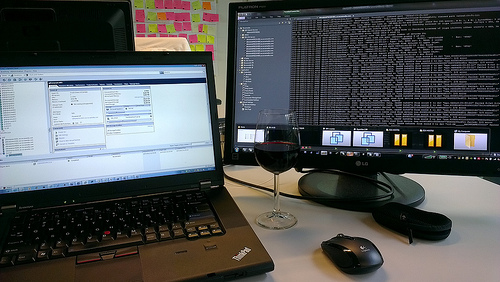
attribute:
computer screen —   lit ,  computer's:
[220, 0, 497, 177]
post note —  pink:
[181, 18, 194, 32]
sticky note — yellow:
[143, 5, 160, 24]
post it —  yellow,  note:
[142, 10, 157, 22]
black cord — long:
[219, 170, 274, 197]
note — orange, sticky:
[202, 0, 212, 10]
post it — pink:
[135, 10, 145, 20]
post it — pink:
[136, 23, 146, 32]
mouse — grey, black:
[314, 225, 392, 271]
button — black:
[168, 218, 185, 231]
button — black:
[199, 225, 211, 237]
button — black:
[113, 228, 128, 238]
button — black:
[144, 223, 156, 235]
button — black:
[136, 206, 146, 218]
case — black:
[365, 184, 478, 259]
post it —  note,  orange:
[156, 10, 177, 22]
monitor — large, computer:
[226, 0, 499, 173]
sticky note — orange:
[202, 0, 214, 10]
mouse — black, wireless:
[316, 211, 369, 278]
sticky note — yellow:
[136, 9, 142, 21]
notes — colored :
[128, 2, 228, 46]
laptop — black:
[27, 40, 301, 240]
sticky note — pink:
[204, 31, 218, 47]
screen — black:
[214, 12, 496, 200]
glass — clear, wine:
[254, 107, 301, 229]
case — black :
[367, 195, 469, 255]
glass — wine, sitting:
[264, 115, 289, 194]